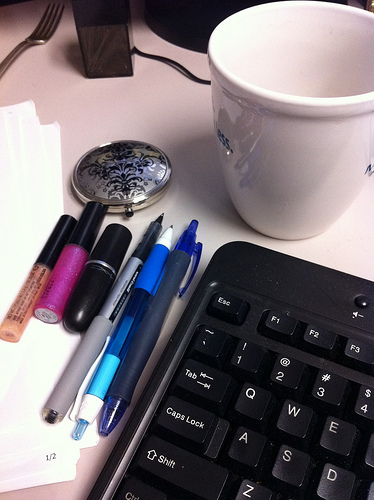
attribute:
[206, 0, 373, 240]
cup — white, empty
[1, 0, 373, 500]
desktop — white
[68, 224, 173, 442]
pen — blue, black,blue, grey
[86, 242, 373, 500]
keyboard — black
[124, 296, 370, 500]
characters — white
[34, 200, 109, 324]
container — pink, black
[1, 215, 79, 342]
container — peach, black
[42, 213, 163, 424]
pen — black, gray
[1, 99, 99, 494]
papers — white, piled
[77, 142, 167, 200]
design — silver, black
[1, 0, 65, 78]
fork — metal, silver, clean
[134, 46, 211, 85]
cord — black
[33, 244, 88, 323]
lip gloss — fuscia, pink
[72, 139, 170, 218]
pocket watch — embossed, silver, compact, black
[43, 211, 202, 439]
pens — multi-colored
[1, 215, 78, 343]
lip gloss — peach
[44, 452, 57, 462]
numbers — black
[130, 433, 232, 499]
shift key — black, white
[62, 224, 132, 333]
lipstick — black, small